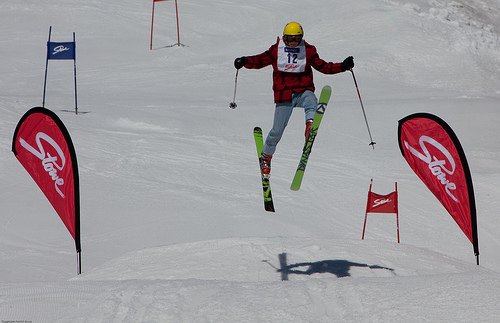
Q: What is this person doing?
A: Skiing.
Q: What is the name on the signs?
A: Stowe.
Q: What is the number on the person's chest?
A: Twelve.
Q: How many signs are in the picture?
A: Five signs.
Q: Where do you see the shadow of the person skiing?
A: Below their body.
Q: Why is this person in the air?
A: They are skiing.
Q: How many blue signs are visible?
A: One sign.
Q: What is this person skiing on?
A: Snow.